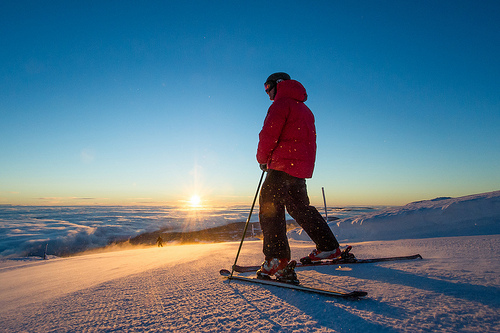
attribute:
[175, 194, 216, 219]
sun — setting, shining, bright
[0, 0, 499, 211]
sky — bright, clear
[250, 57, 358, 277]
man — holding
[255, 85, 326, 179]
jacket — red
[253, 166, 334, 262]
pants — black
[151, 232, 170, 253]
person — skiing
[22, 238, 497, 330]
snow — shadowy, mounding, tracked, white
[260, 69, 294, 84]
helmet — black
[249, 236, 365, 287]
boots — orange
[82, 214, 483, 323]
mountain — covered, plain